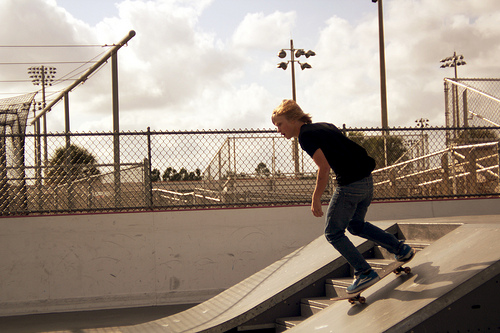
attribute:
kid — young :
[276, 82, 435, 304]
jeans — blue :
[323, 175, 400, 293]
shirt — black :
[296, 119, 385, 187]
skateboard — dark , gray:
[330, 240, 424, 300]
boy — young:
[274, 89, 424, 243]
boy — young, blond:
[263, 96, 414, 283]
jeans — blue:
[324, 182, 411, 274]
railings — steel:
[0, 124, 500, 206]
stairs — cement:
[275, 218, 461, 330]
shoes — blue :
[338, 240, 417, 291]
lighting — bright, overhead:
[22, 59, 64, 95]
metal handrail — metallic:
[149, 184, 226, 213]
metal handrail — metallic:
[328, 133, 495, 199]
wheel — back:
[395, 263, 403, 271]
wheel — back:
[403, 269, 413, 279]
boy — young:
[268, 96, 420, 296]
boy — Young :
[271, 92, 421, 309]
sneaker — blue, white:
[346, 265, 381, 295]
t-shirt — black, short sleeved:
[300, 122, 372, 184]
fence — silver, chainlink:
[0, 125, 498, 217]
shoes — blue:
[339, 240, 426, 321]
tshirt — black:
[298, 120, 378, 181]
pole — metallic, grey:
[288, 37, 299, 177]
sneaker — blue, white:
[394, 240, 415, 260]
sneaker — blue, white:
[346, 271, 378, 291]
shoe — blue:
[392, 241, 415, 260]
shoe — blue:
[346, 263, 379, 295]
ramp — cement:
[282, 221, 499, 330]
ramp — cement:
[126, 219, 398, 330]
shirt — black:
[298, 122, 376, 187]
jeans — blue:
[324, 171, 400, 278]